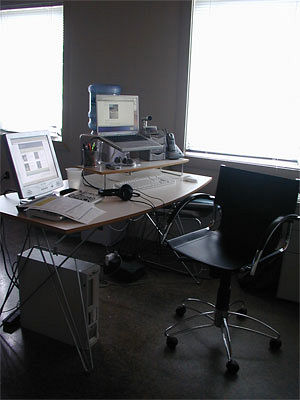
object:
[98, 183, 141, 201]
headphones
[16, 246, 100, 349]
computer tower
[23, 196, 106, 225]
papers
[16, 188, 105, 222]
keyboard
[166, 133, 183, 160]
phone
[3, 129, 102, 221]
computer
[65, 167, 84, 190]
cup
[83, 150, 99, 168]
cup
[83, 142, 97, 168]
pens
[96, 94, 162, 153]
laptop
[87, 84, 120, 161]
water dispenser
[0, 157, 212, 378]
desk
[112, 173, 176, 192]
keyboard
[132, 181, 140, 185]
key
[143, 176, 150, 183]
key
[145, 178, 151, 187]
key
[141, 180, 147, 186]
key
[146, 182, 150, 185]
key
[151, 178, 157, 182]
key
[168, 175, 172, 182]
key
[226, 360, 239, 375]
wheel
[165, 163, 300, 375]
chair